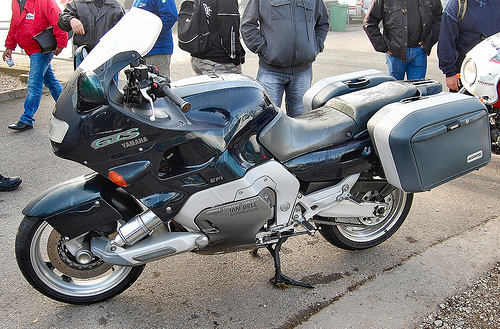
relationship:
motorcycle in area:
[16, 5, 493, 304] [2, 0, 500, 329]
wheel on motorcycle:
[14, 201, 147, 308] [16, 5, 493, 304]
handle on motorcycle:
[157, 80, 192, 114] [16, 5, 493, 304]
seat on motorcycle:
[258, 81, 418, 163] [16, 5, 493, 304]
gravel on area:
[422, 307, 466, 329] [2, 0, 500, 329]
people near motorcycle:
[2, 1, 499, 130] [16, 5, 493, 304]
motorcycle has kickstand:
[16, 5, 493, 304] [249, 237, 315, 292]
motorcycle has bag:
[16, 5, 493, 304] [365, 90, 492, 193]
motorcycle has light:
[16, 5, 493, 304] [49, 114, 71, 144]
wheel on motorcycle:
[14, 207, 146, 307] [16, 5, 493, 304]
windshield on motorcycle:
[79, 7, 163, 95] [16, 5, 493, 304]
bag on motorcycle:
[365, 90, 494, 191] [16, 5, 493, 304]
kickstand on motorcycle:
[249, 237, 315, 292] [16, 5, 493, 304]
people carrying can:
[2, 1, 499, 130] [3, 53, 19, 69]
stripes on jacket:
[455, 2, 473, 23] [437, 1, 499, 78]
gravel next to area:
[422, 307, 466, 329] [2, 0, 500, 329]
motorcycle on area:
[16, 5, 493, 304] [2, 0, 500, 329]